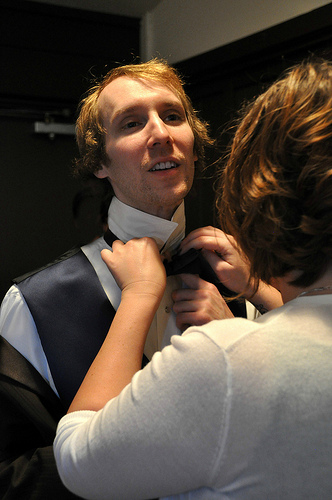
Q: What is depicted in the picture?
A: Left sleeve of white shirt.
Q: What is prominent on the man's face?
A: Cheekbones.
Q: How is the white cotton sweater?
A: Quarter length sleeve.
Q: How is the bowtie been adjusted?
A: By two hands.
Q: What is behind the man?
A: Wall with black paint.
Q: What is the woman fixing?
A: A man's tie.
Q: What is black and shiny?
A: A vest.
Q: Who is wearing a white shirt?
A: The man.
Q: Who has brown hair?
A: The man.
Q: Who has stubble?
A: The man.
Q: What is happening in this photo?
A: Someone is having a tie put on them.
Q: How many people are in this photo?
A: Two.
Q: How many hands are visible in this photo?
A: Three.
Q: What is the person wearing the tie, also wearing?
A: A suit.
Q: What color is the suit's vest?
A: Black.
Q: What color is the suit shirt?
A: White.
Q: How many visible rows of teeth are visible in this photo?
A: One.